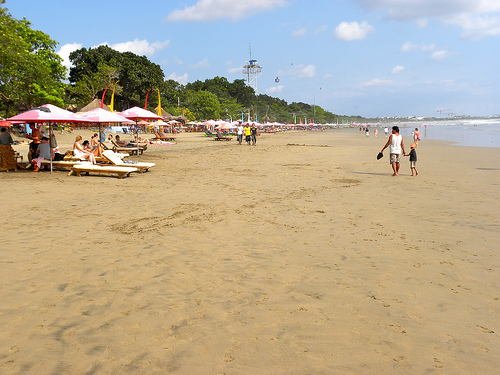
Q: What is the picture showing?
A: It is showing a beach.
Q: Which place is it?
A: It is a beach.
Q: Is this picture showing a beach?
A: Yes, it is showing a beach.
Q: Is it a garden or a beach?
A: It is a beach.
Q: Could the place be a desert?
A: No, it is a beach.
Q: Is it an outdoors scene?
A: Yes, it is outdoors.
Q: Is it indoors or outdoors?
A: It is outdoors.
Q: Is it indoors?
A: No, it is outdoors.